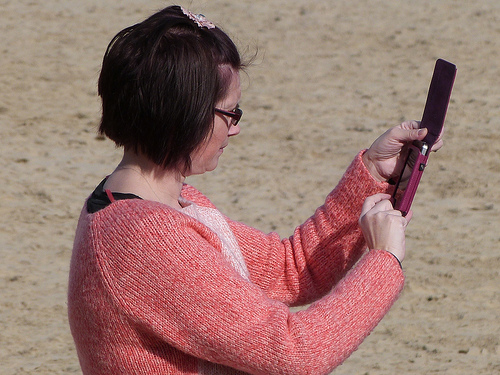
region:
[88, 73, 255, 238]
this is a woman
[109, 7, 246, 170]
this is a bob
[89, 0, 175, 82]
the woman is brunette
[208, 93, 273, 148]
these are glasses that are plastic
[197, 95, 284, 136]
the glasses are black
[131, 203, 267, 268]
this is a sweater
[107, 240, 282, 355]
the sweater is pink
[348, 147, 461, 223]
this is a phone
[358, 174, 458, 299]
this is a hand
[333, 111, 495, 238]
this is a wrist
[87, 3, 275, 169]
A woman with black hair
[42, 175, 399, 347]
A peach colored sweater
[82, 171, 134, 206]
A black shirt under sweater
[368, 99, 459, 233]
A woman holding a cell phone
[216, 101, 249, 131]
A pair of glasses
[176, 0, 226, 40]
A flower decoration in womans hair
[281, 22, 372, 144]
Sandy ground in the background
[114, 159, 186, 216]
A thin necklace on womans neck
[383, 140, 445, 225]
A plum colored cell phone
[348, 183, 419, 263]
Hand pushing buttons on phone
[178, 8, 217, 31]
The lady have a pink bow in her head.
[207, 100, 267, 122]
The woman is wearing glasses.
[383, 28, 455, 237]
The woman is holding a cellphone.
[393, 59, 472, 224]
the cellphone is pink.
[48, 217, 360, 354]
The lady is wearing a red sweater.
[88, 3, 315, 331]
The lady is standing.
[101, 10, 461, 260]
The lady is texting on cell phone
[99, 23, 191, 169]
The lady hair is cut in a bob.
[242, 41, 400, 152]
Sand on the ground.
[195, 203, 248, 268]
A pink shirt under the sweater.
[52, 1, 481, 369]
woman looking at game system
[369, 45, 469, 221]
game system is pink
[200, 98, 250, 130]
woman wearing eye glasses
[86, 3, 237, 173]
woman's hair is brown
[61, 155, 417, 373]
woman's shirt is pink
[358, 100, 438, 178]
woman's left hand on top of game system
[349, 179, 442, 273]
woman's right hand on bottom of system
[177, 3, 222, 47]
hair piece in woman's hair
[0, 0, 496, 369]
sand surrounding the woman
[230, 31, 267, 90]
woman's hair sticking up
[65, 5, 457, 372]
woman is wearing a pink sweater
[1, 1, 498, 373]
brown sand behind woman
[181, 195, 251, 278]
light colored panel is part of the sweater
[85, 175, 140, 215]
black shirt under sweater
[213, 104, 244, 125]
woman wearing glasses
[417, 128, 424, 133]
fingernail attached to thumb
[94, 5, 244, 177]
dark brown hair on top of head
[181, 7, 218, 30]
barrette holding back hair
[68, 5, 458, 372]
woman holding a cell phone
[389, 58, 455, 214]
purple case on top of cell phone